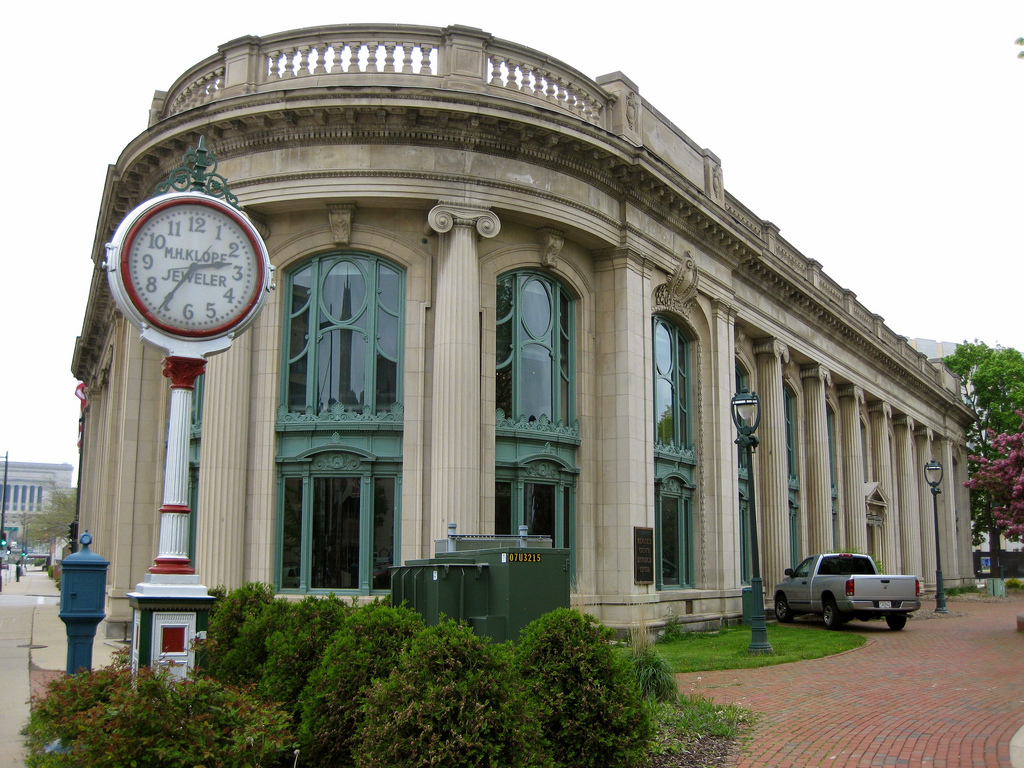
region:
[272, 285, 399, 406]
window on the building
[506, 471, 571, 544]
window on the building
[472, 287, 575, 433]
window on the building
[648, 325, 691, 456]
window on the building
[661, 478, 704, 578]
window on the building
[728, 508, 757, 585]
window on the building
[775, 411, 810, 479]
window on the building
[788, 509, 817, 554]
window on the building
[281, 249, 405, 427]
window with greenmetal frame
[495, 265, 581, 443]
window with greenmetal frame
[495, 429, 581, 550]
window with greenmetal frame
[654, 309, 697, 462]
window with greenmetal frame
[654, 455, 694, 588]
window with greenmetal frame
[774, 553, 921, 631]
grey pickup truck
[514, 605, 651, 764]
a short green bush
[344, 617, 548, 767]
a short green bush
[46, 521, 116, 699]
a bright blue post with a decorative top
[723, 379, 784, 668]
an outdoor light on a green pole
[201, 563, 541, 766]
a row of large green shrubs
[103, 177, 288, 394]
a red and white clock on a pole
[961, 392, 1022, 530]
a tree covered in pink flowers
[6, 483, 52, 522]
a row of white marble pillars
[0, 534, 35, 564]
a few spaced out green traffic lights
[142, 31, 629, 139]
a decorative stone fence on the roof of a building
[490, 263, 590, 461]
a tall, decorative window with a green frame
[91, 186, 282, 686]
standing red and white clock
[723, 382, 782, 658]
green street light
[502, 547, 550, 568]
yellow number on side of green metal box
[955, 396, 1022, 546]
lavender tree flowers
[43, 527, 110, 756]
blue metal pole on the sidewalk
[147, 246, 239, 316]
black time arrows in clock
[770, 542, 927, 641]
A silver truck parked near a building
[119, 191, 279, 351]
A clock on a pole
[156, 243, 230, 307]
Hands on a clock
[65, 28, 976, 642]
A building in the city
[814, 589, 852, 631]
A wheel on a truck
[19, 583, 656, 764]
Green shrubs in front of a building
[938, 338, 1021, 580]
Trees beside a building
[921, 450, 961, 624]
A street light beside a building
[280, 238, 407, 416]
A window on a building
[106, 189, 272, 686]
a nice clock on the outside of a building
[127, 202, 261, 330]
the clock face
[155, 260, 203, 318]
the minute hand of the clock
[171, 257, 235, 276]
the hour hand of the clock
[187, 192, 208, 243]
the 12 o'clock position of theclock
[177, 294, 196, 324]
the 6 o'clock position of theclock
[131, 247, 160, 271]
the 9 o'clock position of theclock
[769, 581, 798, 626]
the vehicles front tire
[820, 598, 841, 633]
the vehicles rear tire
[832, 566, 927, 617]
the rear part of the vehicle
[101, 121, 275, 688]
White post with round clock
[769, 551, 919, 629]
Gre truck with black windows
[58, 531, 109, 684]
Blue post or meter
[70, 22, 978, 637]
Long beidge building with balcony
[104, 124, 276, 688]
White clock post showing 2:35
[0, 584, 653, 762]
Green bushes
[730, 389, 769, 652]
Green light post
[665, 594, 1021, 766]
Long brick path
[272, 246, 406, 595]
Large Window with green borders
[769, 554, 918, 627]
Licence plate on grey truck